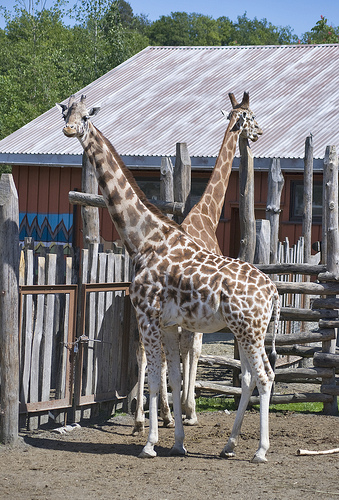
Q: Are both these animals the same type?
A: Yes, all the animals are giraffes.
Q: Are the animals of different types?
A: No, all the animals are giraffes.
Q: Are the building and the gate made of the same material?
A: Yes, both the building and the gate are made of metal.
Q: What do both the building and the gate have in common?
A: The material, both the building and the gate are metallic.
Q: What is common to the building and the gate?
A: The material, both the building and the gate are metallic.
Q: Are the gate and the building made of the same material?
A: Yes, both the gate and the building are made of metal.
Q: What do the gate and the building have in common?
A: The material, both the gate and the building are metallic.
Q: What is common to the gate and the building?
A: The material, both the gate and the building are metallic.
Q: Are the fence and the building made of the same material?
A: No, the fence is made of wood and the building is made of metal.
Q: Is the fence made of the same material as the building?
A: No, the fence is made of wood and the building is made of metal.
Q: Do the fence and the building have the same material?
A: No, the fence is made of wood and the building is made of metal.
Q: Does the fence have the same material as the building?
A: No, the fence is made of wood and the building is made of metal.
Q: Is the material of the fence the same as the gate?
A: No, the fence is made of wood and the gate is made of metal.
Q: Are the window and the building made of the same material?
A: No, the window is made of glass and the building is made of metal.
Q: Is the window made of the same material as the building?
A: No, the window is made of glass and the building is made of metal.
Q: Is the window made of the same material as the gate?
A: No, the window is made of glass and the gate is made of metal.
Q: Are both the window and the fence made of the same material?
A: No, the window is made of glass and the fence is made of wood.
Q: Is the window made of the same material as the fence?
A: No, the window is made of glass and the fence is made of wood.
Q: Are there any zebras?
A: No, there are no zebras.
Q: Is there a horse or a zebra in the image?
A: No, there are no zebras or horses.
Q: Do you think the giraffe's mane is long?
A: Yes, the mane is long.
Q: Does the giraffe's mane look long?
A: Yes, the mane is long.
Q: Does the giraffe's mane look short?
A: No, the mane is long.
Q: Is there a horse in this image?
A: No, there are no horses.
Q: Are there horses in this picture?
A: No, there are no horses.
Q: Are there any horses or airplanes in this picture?
A: No, there are no horses or airplanes.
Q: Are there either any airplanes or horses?
A: No, there are no horses or airplanes.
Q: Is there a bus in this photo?
A: No, there are no buses.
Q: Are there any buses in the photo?
A: No, there are no buses.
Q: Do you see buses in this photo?
A: No, there are no buses.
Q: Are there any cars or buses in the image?
A: No, there are no buses or cars.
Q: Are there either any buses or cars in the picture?
A: No, there are no buses or cars.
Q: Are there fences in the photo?
A: Yes, there is a fence.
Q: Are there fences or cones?
A: Yes, there is a fence.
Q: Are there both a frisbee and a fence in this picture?
A: No, there is a fence but no frisbees.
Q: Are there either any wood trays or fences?
A: Yes, there is a wood fence.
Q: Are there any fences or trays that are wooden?
A: Yes, the fence is wooden.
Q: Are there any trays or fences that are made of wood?
A: Yes, the fence is made of wood.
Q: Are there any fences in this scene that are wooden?
A: Yes, there is a wood fence.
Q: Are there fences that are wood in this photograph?
A: Yes, there is a wood fence.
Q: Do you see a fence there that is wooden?
A: Yes, there is a fence that is wooden.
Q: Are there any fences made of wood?
A: Yes, there is a fence that is made of wood.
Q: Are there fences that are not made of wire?
A: Yes, there is a fence that is made of wood.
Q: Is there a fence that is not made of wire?
A: Yes, there is a fence that is made of wood.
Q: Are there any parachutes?
A: No, there are no parachutes.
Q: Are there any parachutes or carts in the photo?
A: No, there are no parachutes or carts.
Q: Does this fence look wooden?
A: Yes, the fence is wooden.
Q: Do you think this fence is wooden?
A: Yes, the fence is wooden.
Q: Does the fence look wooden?
A: Yes, the fence is wooden.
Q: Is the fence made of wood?
A: Yes, the fence is made of wood.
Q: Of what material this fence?
A: The fence is made of wood.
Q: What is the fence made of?
A: The fence is made of wood.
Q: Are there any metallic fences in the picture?
A: No, there is a fence but it is wooden.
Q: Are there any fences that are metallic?
A: No, there is a fence but it is wooden.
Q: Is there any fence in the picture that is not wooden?
A: No, there is a fence but it is wooden.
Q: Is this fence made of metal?
A: No, the fence is made of wood.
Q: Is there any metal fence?
A: No, there is a fence but it is made of wood.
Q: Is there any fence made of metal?
A: No, there is a fence but it is made of wood.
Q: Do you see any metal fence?
A: No, there is a fence but it is made of wood.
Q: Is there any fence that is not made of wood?
A: No, there is a fence but it is made of wood.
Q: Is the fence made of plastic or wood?
A: The fence is made of wood.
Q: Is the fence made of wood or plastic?
A: The fence is made of wood.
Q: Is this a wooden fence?
A: Yes, this is a wooden fence.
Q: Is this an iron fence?
A: No, this is a wooden fence.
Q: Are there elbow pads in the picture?
A: No, there are no elbow pads.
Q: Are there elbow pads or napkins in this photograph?
A: No, there are no elbow pads or napkins.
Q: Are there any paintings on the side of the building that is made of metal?
A: Yes, there is a painting on the side of the building.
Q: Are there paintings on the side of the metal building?
A: Yes, there is a painting on the side of the building.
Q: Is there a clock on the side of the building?
A: No, there is a painting on the side of the building.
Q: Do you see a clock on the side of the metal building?
A: No, there is a painting on the side of the building.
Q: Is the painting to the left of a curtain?
A: No, the painting is to the left of a giraffe.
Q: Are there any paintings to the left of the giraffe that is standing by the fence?
A: Yes, there is a painting to the left of the giraffe.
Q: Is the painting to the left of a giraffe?
A: Yes, the painting is to the left of a giraffe.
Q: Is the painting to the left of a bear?
A: No, the painting is to the left of a giraffe.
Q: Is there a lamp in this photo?
A: No, there are no lamps.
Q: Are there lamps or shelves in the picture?
A: No, there are no lamps or shelves.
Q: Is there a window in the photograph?
A: Yes, there is a window.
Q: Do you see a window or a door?
A: Yes, there is a window.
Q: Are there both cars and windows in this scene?
A: No, there is a window but no cars.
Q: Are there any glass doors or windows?
A: Yes, there is a glass window.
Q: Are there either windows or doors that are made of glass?
A: Yes, the window is made of glass.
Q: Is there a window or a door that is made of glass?
A: Yes, the window is made of glass.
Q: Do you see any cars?
A: No, there are no cars.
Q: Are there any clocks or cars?
A: No, there are no cars or clocks.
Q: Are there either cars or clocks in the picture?
A: No, there are no cars or clocks.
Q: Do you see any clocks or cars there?
A: No, there are no cars or clocks.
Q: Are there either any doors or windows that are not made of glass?
A: No, there is a window but it is made of glass.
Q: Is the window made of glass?
A: Yes, the window is made of glass.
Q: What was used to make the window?
A: The window is made of glass.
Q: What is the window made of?
A: The window is made of glass.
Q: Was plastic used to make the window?
A: No, the window is made of glass.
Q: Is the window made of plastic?
A: No, the window is made of glass.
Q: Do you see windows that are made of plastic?
A: No, there is a window but it is made of glass.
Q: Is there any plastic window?
A: No, there is a window but it is made of glass.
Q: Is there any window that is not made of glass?
A: No, there is a window but it is made of glass.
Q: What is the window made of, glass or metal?
A: The window is made of glass.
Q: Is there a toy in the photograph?
A: No, there are no toys.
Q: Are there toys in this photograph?
A: No, there are no toys.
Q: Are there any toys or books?
A: No, there are no toys or books.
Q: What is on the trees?
A: The leaves are on the trees.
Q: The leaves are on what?
A: The leaves are on the trees.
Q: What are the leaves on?
A: The leaves are on the trees.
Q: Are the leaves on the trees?
A: Yes, the leaves are on the trees.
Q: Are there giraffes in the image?
A: Yes, there is a giraffe.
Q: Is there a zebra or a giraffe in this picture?
A: Yes, there is a giraffe.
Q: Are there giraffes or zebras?
A: Yes, there is a giraffe.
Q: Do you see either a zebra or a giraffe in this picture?
A: Yes, there is a giraffe.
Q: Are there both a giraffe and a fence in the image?
A: Yes, there are both a giraffe and a fence.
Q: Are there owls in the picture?
A: No, there are no owls.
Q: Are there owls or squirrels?
A: No, there are no owls or squirrels.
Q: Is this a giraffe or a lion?
A: This is a giraffe.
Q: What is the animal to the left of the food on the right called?
A: The animal is a giraffe.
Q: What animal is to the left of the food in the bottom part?
A: The animal is a giraffe.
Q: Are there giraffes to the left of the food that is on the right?
A: Yes, there is a giraffe to the left of the food.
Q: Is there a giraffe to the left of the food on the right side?
A: Yes, there is a giraffe to the left of the food.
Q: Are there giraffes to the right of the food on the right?
A: No, the giraffe is to the left of the food.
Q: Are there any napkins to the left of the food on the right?
A: No, there is a giraffe to the left of the food.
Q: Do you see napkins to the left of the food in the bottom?
A: No, there is a giraffe to the left of the food.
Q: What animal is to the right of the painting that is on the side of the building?
A: The animal is a giraffe.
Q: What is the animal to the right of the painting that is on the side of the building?
A: The animal is a giraffe.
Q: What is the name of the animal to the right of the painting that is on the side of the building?
A: The animal is a giraffe.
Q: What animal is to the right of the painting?
A: The animal is a giraffe.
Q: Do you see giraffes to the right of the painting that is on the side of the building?
A: Yes, there is a giraffe to the right of the painting.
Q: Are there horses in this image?
A: No, there are no horses.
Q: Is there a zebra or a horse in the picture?
A: No, there are no horses or zebras.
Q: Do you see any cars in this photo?
A: No, there are no cars.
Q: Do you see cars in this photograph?
A: No, there are no cars.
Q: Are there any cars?
A: No, there are no cars.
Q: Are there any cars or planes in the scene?
A: No, there are no cars or planes.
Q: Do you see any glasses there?
A: No, there are no glasses.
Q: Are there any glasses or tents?
A: No, there are no glasses or tents.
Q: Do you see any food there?
A: Yes, there is food.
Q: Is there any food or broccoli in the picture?
A: Yes, there is food.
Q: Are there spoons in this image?
A: No, there are no spoons.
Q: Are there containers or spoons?
A: No, there are no spoons or containers.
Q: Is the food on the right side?
A: Yes, the food is on the right of the image.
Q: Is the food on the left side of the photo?
A: No, the food is on the right of the image.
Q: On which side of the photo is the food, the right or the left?
A: The food is on the right of the image.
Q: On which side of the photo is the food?
A: The food is on the right of the image.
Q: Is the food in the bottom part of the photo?
A: Yes, the food is in the bottom of the image.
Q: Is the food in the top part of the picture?
A: No, the food is in the bottom of the image.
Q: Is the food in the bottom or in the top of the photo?
A: The food is in the bottom of the image.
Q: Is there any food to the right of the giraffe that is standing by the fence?
A: Yes, there is food to the right of the giraffe.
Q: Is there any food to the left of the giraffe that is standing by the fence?
A: No, the food is to the right of the giraffe.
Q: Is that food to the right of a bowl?
A: No, the food is to the right of the giraffe.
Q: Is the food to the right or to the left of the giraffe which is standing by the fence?
A: The food is to the right of the giraffe.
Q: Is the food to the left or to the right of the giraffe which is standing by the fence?
A: The food is to the right of the giraffe.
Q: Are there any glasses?
A: No, there are no glasses.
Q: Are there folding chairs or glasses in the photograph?
A: No, there are no glasses or folding chairs.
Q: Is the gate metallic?
A: Yes, the gate is metallic.